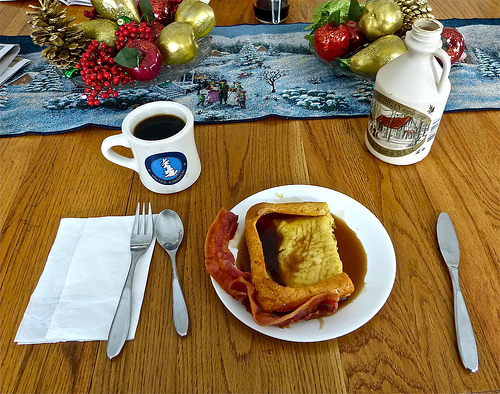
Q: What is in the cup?
A: Coffee.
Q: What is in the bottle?
A: Syrup.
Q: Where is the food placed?
A: Plate.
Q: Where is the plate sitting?
A: Table.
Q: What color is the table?
A: Brown.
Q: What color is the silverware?
A: Silver.